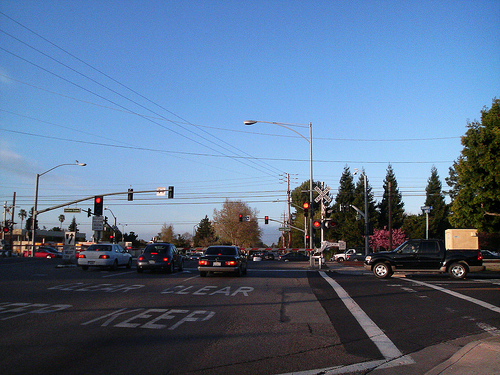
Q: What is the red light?
A: Traffic signal.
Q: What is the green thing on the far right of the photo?
A: Tree.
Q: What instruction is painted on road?
A: KEEP CLEAR.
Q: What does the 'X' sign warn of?
A: Railroad crossing.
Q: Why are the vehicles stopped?
A: Train.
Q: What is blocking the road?
A: Railroad crossing arm.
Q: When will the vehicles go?
A: After train passes.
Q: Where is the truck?
A: Right.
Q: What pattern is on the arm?
A: Stripes.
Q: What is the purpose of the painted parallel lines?
A: Crosswalk.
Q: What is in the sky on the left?
A: Clouds.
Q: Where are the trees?
A: In background.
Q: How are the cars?
A: Stopped.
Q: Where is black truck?
A: To right.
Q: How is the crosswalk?
A: Painted.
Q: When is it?
A: Daytime.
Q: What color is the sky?
A: Blue.